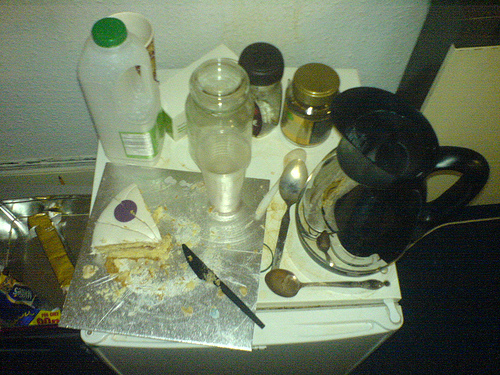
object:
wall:
[0, 2, 95, 165]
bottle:
[76, 17, 164, 169]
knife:
[181, 242, 265, 328]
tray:
[62, 161, 269, 354]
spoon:
[264, 270, 385, 297]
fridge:
[257, 268, 404, 334]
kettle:
[297, 87, 490, 277]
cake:
[90, 183, 163, 259]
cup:
[112, 12, 156, 82]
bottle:
[240, 42, 284, 126]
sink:
[1, 188, 82, 326]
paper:
[1, 275, 60, 325]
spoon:
[272, 158, 309, 274]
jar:
[187, 59, 251, 174]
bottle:
[280, 64, 340, 148]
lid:
[294, 63, 341, 98]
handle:
[137, 48, 156, 96]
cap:
[92, 18, 128, 48]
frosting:
[92, 184, 164, 244]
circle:
[113, 199, 138, 222]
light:
[291, 165, 301, 179]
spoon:
[256, 148, 306, 216]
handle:
[416, 145, 488, 223]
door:
[82, 305, 399, 375]